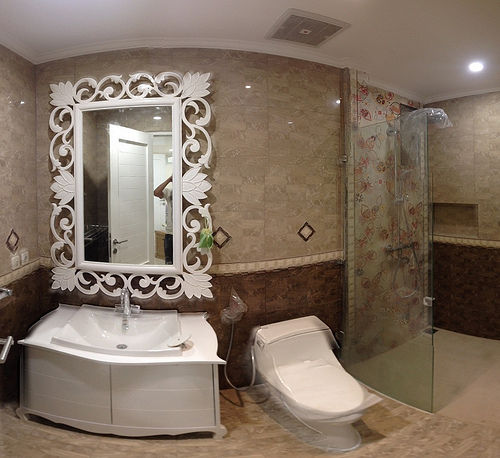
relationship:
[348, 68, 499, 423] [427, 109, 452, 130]
shower has shower head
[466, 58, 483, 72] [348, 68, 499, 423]
light inside shower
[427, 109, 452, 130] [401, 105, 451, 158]
shower head has bag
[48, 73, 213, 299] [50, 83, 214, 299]
mirror has frame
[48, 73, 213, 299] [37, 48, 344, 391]
mirror on wall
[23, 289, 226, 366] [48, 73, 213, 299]
sink below mirror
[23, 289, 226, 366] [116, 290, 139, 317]
sink has faucet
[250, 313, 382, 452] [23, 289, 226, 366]
toilet next to sink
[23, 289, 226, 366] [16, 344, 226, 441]
sink has bottom part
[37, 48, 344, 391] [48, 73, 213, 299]
wall next to mirror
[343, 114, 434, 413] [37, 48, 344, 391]
partition next to wall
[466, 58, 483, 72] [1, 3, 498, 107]
light on ceiling